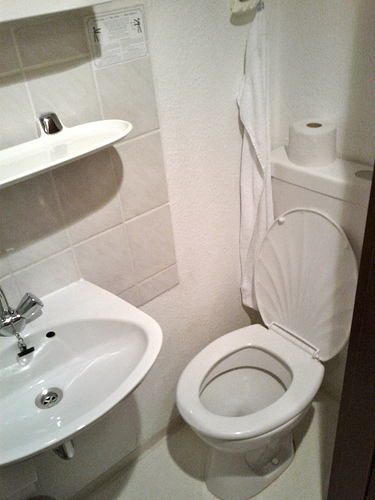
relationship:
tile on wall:
[124, 201, 176, 286] [0, 0, 265, 498]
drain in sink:
[35, 387, 63, 408] [2, 279, 161, 464]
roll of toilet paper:
[289, 119, 337, 167] [292, 136, 332, 155]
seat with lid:
[176, 324, 325, 441] [234, 209, 364, 361]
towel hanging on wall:
[226, 41, 288, 329] [158, 53, 248, 288]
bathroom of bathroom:
[0, 0, 375, 500] [11, 35, 366, 484]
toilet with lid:
[153, 213, 354, 469] [249, 202, 356, 360]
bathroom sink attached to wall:
[0, 299, 163, 465] [0, 203, 130, 258]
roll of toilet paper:
[303, 122, 324, 130] [295, 139, 325, 153]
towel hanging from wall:
[234, 9, 273, 314] [175, 65, 231, 197]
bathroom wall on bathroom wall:
[8, 187, 165, 278] [10, 6, 248, 282]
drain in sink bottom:
[12, 381, 67, 402] [14, 338, 113, 410]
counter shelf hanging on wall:
[0, 118, 132, 189] [0, 6, 160, 242]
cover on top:
[271, 144, 372, 203] [271, 151, 369, 191]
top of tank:
[271, 151, 369, 191] [254, 132, 373, 267]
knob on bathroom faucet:
[0, 310, 36, 322] [0, 291, 44, 337]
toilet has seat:
[175, 205, 360, 499] [193, 329, 306, 437]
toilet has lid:
[175, 205, 360, 499] [246, 210, 363, 360]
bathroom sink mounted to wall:
[0, 299, 163, 465] [0, 47, 153, 288]